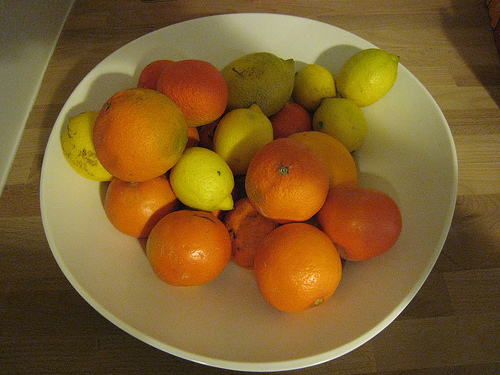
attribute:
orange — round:
[252, 220, 342, 313]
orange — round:
[146, 209, 232, 290]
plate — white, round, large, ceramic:
[39, 14, 460, 374]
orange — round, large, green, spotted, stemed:
[93, 87, 189, 181]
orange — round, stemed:
[246, 137, 329, 224]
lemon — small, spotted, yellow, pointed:
[335, 49, 398, 107]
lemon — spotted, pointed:
[169, 147, 234, 212]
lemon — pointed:
[310, 96, 366, 153]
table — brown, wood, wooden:
[0, 1, 498, 374]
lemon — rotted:
[63, 112, 110, 186]